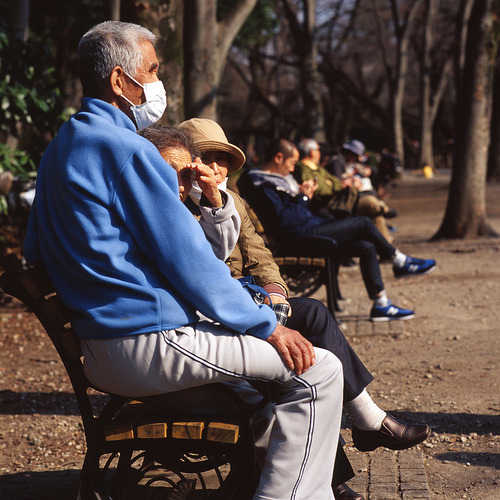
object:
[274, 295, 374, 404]
pants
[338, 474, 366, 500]
shoes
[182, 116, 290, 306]
woman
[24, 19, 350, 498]
man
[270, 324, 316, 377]
man's hand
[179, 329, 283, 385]
thigh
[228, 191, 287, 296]
jacket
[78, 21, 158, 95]
hair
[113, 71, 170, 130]
mask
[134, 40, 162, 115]
face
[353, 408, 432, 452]
shoe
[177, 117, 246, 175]
hat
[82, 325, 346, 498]
pants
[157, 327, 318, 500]
stripe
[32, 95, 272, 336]
shirt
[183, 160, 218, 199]
hand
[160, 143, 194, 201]
face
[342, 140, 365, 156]
hat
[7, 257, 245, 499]
bench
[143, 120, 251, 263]
woman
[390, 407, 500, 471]
shadow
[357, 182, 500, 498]
ground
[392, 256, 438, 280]
shoe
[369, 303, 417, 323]
shoe